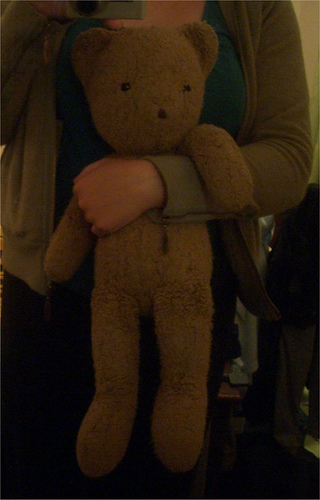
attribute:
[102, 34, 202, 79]
head — top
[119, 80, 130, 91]
eye — larger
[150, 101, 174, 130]
nose — brown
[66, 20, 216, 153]
head — teddy, bear, brown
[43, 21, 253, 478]
bear — black, bear's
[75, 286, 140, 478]
leg — brown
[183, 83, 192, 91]
black eye — smaller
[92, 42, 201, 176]
face — bear's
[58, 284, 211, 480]
legs — brown